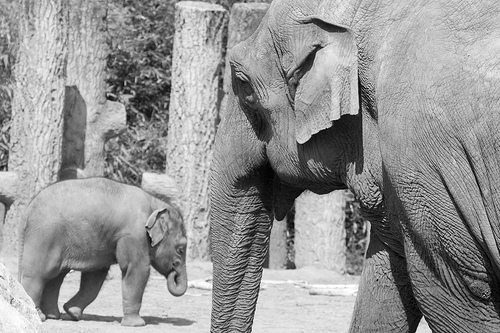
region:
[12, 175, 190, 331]
light gray colored baby elephant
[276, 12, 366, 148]
adult elephant ear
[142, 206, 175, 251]
baby elephant's ear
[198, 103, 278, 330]
adult elephant's trunk hanging straight down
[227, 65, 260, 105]
dark colored adult elephant's eye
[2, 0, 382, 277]
forest of trees located behind view of elephants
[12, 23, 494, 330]
dark colored mother elephant with lighter colored baby elephant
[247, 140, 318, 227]
adult elephant's mouth which looks like smile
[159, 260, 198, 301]
baby elephant trunk curled into it's mouth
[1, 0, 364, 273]
leafy younger trees and bushes located behind mature trees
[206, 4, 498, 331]
the elephant is large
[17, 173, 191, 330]
the baby elephant is small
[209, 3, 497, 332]
the elephant has an eye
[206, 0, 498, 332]
the elephant is wrinkly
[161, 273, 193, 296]
the trunk is curled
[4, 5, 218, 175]
the tree trunk is grey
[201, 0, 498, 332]
the elephant has an ear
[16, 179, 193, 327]
the baby elephant has an ear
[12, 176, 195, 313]
the baby elephant is standing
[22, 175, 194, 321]
the baby elephant is raising its leg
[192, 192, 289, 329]
elephant front tail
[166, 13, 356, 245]
face of the elephant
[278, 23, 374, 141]
ear of the elephant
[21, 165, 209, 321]
a small elephant in ground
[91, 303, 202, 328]
shadow of the elephant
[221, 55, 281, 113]
eye of the elephant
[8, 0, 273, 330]
a large trees on back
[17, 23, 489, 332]
two small and big elephants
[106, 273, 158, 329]
leg of the small elephant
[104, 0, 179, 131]
a small part of trees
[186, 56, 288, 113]
the eye of a elephant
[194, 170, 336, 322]
the trunk of a elephant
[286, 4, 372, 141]
the ear of a elephant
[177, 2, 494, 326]
a big grey elephant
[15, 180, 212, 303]
a grey baby elephant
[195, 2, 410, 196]
the head of a elephant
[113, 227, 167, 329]
the front leg of a elephant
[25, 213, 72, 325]
the back legs of a elephant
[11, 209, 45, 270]
the tail of a elephant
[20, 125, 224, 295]
a elephant near a tree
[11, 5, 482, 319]
the picture is black and white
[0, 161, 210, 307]
the elephant is small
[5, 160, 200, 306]
the elephant is a baby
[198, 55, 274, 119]
the eye is open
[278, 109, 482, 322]
the skin is wrinkled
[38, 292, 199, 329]
shadow of the elephant on the ground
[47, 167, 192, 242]
the elephant has hair on it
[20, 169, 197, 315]
the elephant is walking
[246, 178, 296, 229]
the mouth is slightly open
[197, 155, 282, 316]
the trunk is thick